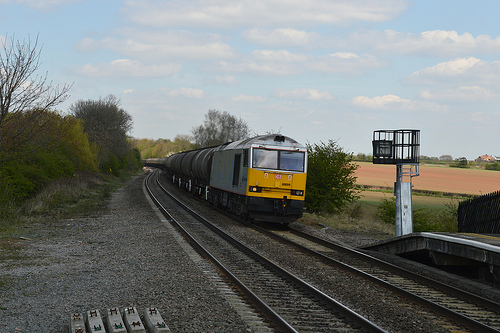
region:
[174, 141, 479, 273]
This is a train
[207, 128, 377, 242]
The train is yellow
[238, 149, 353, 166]
This is a window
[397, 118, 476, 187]
This is a lift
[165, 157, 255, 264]
This is a track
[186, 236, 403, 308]
The track is black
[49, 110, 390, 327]
The track is made of steel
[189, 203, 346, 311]
The track has rust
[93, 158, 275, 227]
These are train cars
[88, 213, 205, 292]
These are small stones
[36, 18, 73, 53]
this is the sky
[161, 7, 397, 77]
the sky has clouds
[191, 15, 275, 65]
the clouds are white in color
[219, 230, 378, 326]
this is a railway line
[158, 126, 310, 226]
this is a train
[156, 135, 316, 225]
the train is on the railway line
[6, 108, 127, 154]
these are some bushes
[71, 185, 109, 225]
this is the grass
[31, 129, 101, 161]
the leaves are green in color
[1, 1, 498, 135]
white clouds in sky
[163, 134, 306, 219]
yellow on front of train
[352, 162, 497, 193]
surface of flat land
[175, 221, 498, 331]
two sets of train tracks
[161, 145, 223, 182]
tanks of freight train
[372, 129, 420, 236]
elevated metal platform with railing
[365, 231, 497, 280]
ramp on side of tracks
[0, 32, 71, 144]
tree with no leaves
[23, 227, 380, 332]
gravel in between tracks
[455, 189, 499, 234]
side of wood fence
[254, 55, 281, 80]
part of a cloud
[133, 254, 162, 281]
part of a ground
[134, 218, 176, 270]
aprt of a ground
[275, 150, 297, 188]
part of a trainm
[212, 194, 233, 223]
aprt of a rail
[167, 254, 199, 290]
part of a ground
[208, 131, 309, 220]
a yellow and gray train engine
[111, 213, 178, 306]
gravel alongside the tracks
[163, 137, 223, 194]
tanker cars pulled behind an engine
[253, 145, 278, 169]
the front window of an engine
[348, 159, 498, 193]
a brown plowed field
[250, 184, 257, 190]
a headlight on the front of a train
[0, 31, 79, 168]
a bare leafless tree near the train tracks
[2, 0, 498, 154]
a blue and white cloudy sky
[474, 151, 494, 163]
a house in the distance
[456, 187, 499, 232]
a wood fence alongside a ramp